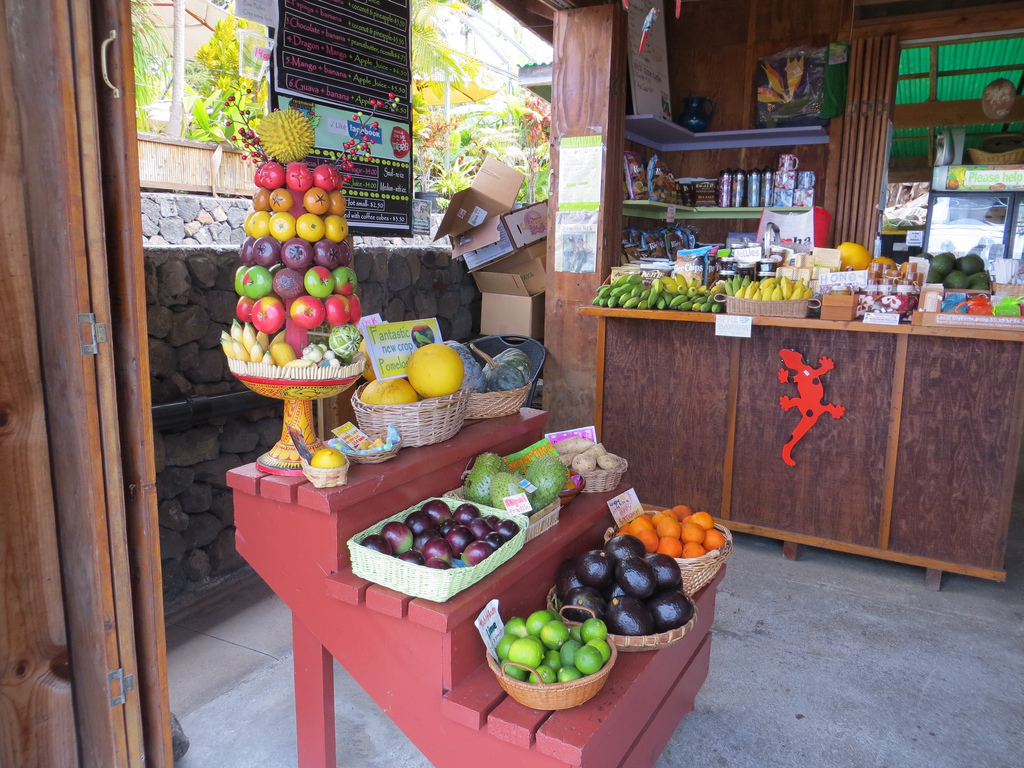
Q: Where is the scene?
A: In a fruit market.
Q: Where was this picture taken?
A: Store.